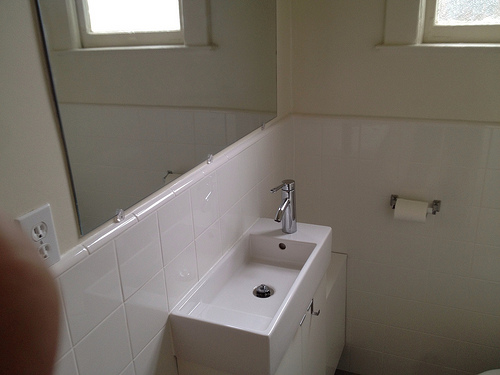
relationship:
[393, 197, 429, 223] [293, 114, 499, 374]
toilet paper on wall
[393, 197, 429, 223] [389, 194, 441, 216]
toilet paper on mounted dispenser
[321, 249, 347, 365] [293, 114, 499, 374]
receptacle on side of wall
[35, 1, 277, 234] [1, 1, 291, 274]
mirror mounted on tan wall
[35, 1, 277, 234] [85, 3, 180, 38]
mirror reflecting window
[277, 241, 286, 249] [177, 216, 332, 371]
hole in sink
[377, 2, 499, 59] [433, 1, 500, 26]
frame around window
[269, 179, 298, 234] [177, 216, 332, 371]
faucet on sink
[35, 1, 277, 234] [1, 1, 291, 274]
mirror hanging on wall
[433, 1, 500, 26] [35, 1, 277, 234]
window reflected in mirror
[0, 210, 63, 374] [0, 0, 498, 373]
fingertip in photo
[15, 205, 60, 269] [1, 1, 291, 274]
electrical outlet in tan wall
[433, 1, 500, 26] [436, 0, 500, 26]
window has crackled glass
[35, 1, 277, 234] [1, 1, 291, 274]
mirror on tan wall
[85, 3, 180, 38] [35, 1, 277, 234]
window reflecting in mirror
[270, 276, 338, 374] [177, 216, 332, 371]
cabinet under sink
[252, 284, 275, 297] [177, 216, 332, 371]
drain in bottom of sink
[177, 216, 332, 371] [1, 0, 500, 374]
sink in bathroom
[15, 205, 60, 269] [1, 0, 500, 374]
electrical outlet in bathroom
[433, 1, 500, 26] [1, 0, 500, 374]
window in bathroom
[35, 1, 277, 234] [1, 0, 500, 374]
mirror in bathroom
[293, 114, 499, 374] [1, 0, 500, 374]
wall in bathroom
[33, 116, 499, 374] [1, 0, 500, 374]
wall tiles are in bathroom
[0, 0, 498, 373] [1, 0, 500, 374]
picture of bathroom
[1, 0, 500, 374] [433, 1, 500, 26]
bathroom has window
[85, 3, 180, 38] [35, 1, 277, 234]
window reflected in mirror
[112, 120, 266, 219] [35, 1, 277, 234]
plastic pegs are holding mirror